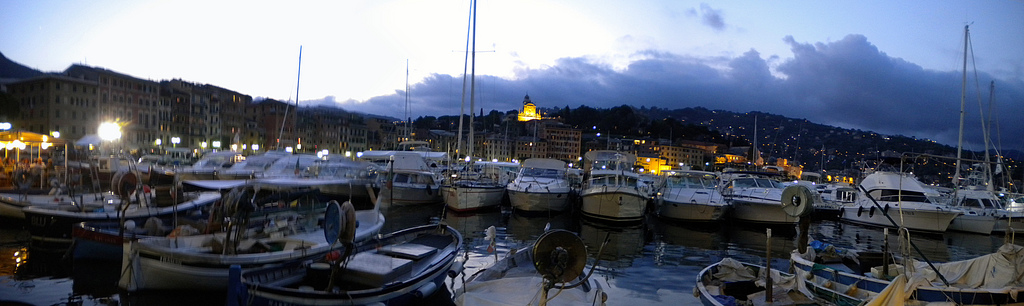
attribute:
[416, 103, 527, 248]
boat — white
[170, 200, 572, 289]
boat — white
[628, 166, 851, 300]
boat — white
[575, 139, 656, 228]
boat — white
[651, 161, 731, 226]
boat — white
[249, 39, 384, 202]
boat — white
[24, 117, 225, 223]
boat — one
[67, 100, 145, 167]
light — one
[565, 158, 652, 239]
boat — one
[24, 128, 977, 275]
water — some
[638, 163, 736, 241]
boat — one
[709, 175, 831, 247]
boat — one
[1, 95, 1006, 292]
water — some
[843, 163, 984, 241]
boat — one